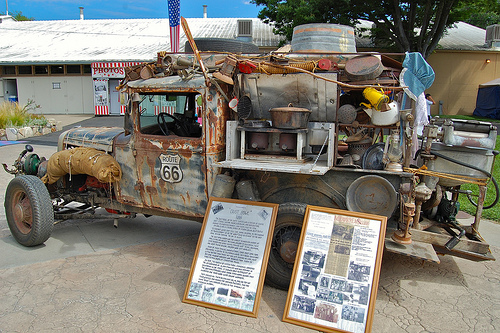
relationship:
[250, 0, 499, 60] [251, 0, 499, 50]
tree with leaves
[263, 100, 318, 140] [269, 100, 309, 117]
pot with lid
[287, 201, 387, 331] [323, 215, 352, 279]
collage with newspaper clipping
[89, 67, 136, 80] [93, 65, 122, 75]
sign says photos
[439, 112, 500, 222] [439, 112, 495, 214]
grass of grass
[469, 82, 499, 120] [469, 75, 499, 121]
tent of tent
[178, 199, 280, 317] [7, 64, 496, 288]
frame against truck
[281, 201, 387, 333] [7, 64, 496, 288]
collage against truck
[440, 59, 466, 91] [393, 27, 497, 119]
wall of building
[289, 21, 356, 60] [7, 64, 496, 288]
basin on truck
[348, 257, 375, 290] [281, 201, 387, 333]
photo in collage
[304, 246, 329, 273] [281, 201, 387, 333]
photo in collage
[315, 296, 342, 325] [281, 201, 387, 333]
photo in collage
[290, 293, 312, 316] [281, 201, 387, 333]
photo in collage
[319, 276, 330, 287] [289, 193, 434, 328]
photo in frame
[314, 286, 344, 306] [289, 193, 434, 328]
photo in frame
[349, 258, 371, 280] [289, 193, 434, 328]
photo in frame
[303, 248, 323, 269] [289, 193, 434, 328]
photo in frame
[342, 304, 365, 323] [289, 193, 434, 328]
photo in frame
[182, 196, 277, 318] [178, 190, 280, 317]
sign in frame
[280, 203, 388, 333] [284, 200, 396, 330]
sign in frame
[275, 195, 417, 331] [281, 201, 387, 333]
sign in collage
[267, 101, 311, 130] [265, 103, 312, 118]
pot with lid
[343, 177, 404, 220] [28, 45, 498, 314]
bucket on truck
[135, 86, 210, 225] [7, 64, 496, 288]
door of truck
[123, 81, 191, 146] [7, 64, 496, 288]
window of truck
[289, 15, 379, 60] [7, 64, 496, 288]
basin on truck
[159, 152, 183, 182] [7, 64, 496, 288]
logo on truck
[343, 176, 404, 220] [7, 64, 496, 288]
bucket on truck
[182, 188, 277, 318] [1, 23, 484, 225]
sign leaning on truck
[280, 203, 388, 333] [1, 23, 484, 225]
sign leaning on truck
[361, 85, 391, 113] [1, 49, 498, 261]
coffeepot on truck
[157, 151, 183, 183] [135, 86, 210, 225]
logo on door